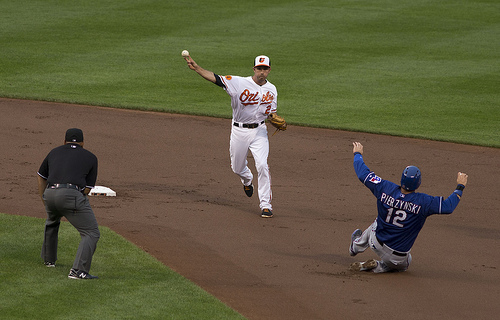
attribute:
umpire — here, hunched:
[23, 108, 135, 284]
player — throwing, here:
[184, 37, 299, 243]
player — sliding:
[326, 126, 482, 305]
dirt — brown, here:
[139, 135, 257, 265]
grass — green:
[114, 15, 201, 89]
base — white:
[82, 176, 127, 201]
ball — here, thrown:
[170, 45, 215, 73]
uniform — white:
[187, 25, 297, 205]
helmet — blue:
[400, 160, 433, 197]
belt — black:
[223, 113, 273, 135]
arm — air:
[179, 54, 220, 91]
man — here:
[199, 23, 295, 220]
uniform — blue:
[369, 155, 439, 255]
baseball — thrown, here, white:
[166, 45, 192, 63]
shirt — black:
[28, 140, 122, 203]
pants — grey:
[33, 187, 113, 283]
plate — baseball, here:
[91, 167, 117, 198]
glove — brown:
[262, 104, 296, 137]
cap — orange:
[253, 50, 278, 75]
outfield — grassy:
[303, 12, 486, 114]